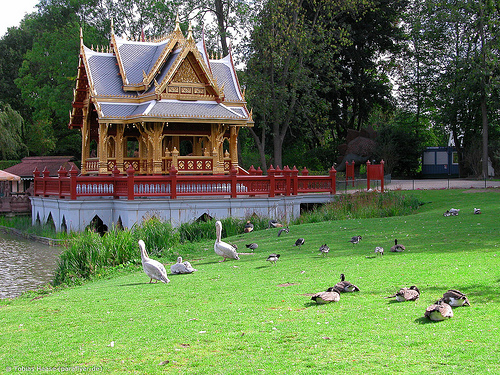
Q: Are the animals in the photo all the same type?
A: No, they are birds and ducks.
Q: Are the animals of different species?
A: Yes, they are birds and ducks.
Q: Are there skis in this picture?
A: No, there are no skis.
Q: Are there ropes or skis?
A: No, there are no skis or ropes.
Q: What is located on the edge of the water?
A: The plants are on the edge of the water.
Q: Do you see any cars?
A: No, there are no cars.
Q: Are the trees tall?
A: Yes, the trees are tall.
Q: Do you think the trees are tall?
A: Yes, the trees are tall.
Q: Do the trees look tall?
A: Yes, the trees are tall.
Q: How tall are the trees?
A: The trees are tall.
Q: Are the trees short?
A: No, the trees are tall.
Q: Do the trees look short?
A: No, the trees are tall.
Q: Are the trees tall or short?
A: The trees are tall.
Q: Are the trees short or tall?
A: The trees are tall.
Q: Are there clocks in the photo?
A: No, there are no clocks.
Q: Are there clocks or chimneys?
A: No, there are no clocks or chimneys.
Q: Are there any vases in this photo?
A: No, there are no vases.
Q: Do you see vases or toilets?
A: No, there are no vases or toilets.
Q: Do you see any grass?
A: Yes, there is grass.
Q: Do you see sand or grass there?
A: Yes, there is grass.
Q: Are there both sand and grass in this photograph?
A: No, there is grass but no sand.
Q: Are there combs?
A: No, there are no combs.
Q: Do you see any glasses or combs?
A: No, there are no combs or glasses.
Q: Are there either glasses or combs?
A: No, there are no combs or glasses.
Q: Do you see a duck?
A: Yes, there is a duck.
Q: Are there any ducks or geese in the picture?
A: Yes, there is a duck.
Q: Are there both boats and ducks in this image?
A: No, there is a duck but no boats.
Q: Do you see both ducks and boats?
A: No, there is a duck but no boats.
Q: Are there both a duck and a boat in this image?
A: No, there is a duck but no boats.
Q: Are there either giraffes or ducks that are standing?
A: Yes, the duck is standing.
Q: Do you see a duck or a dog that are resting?
A: Yes, the duck is resting.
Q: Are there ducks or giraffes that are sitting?
A: Yes, the duck is sitting.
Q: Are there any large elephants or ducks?
A: Yes, there is a large duck.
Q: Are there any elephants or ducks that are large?
A: Yes, the duck is large.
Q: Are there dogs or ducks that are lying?
A: Yes, the duck is lying.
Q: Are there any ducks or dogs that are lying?
A: Yes, the duck is lying.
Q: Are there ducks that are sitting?
A: Yes, there is a duck that is sitting.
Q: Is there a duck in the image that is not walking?
A: Yes, there is a duck that is sitting.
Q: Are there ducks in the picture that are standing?
A: Yes, there is a duck that is standing.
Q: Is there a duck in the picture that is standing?
A: Yes, there is a duck that is standing.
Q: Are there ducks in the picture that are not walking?
A: Yes, there is a duck that is standing.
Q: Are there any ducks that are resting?
A: Yes, there is a duck that is resting.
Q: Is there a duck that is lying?
A: Yes, there is a duck that is lying.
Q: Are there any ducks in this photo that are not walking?
A: Yes, there is a duck that is lying.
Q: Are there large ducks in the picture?
A: Yes, there is a large duck.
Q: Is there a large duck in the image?
A: Yes, there is a large duck.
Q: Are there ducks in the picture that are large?
A: Yes, there is a duck that is large.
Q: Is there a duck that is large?
A: Yes, there is a duck that is large.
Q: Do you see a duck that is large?
A: Yes, there is a duck that is large.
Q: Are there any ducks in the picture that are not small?
A: Yes, there is a large duck.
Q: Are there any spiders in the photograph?
A: No, there are no spiders.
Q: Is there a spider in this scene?
A: No, there are no spiders.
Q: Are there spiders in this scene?
A: No, there are no spiders.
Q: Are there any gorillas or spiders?
A: No, there are no spiders or gorillas.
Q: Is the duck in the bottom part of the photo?
A: Yes, the duck is in the bottom of the image.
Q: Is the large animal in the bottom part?
A: Yes, the duck is in the bottom of the image.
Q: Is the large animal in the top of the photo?
A: No, the duck is in the bottom of the image.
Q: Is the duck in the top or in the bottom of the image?
A: The duck is in the bottom of the image.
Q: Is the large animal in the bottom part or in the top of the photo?
A: The duck is in the bottom of the image.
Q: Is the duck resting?
A: Yes, the duck is resting.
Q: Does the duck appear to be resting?
A: Yes, the duck is resting.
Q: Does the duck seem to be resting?
A: Yes, the duck is resting.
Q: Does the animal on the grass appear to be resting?
A: Yes, the duck is resting.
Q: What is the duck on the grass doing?
A: The duck is resting.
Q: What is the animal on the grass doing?
A: The duck is resting.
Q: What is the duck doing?
A: The duck is resting.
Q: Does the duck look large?
A: Yes, the duck is large.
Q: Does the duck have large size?
A: Yes, the duck is large.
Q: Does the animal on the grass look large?
A: Yes, the duck is large.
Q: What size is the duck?
A: The duck is large.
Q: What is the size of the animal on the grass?
A: The duck is large.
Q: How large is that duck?
A: The duck is large.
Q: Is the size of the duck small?
A: No, the duck is large.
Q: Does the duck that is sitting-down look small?
A: No, the duck is large.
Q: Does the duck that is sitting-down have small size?
A: No, the duck is large.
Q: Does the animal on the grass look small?
A: No, the duck is large.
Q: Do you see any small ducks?
A: No, there is a duck but it is large.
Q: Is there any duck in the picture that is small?
A: No, there is a duck but it is large.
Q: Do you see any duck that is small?
A: No, there is a duck but it is large.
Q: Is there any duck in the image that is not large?
A: No, there is a duck but it is large.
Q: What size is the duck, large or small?
A: The duck is large.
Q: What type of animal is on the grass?
A: The animal is a duck.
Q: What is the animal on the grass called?
A: The animal is a duck.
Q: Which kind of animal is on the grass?
A: The animal is a duck.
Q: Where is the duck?
A: The duck is on the grass.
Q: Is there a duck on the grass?
A: Yes, there is a duck on the grass.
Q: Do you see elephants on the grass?
A: No, there is a duck on the grass.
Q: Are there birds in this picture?
A: Yes, there are birds.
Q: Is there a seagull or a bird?
A: Yes, there are birds.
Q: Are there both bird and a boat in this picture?
A: No, there are birds but no boats.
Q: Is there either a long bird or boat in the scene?
A: Yes, there are long birds.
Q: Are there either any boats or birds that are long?
A: Yes, the birds are long.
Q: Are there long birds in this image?
A: Yes, there are long birds.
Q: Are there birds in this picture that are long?
A: Yes, there are birds that are long.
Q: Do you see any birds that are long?
A: Yes, there are birds that are long.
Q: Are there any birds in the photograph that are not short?
A: Yes, there are long birds.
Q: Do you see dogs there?
A: No, there are no dogs.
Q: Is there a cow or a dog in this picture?
A: No, there are no dogs or cows.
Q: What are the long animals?
A: The animals are birds.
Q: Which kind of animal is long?
A: The animal is birds.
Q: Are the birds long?
A: Yes, the birds are long.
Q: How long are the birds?
A: The birds are long.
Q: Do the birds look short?
A: No, the birds are long.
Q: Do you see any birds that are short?
A: No, there are birds but they are long.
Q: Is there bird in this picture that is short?
A: No, there are birds but they are long.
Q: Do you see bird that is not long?
A: No, there are birds but they are long.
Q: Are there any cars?
A: No, there are no cars.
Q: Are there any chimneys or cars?
A: No, there are no cars or chimneys.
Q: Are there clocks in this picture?
A: No, there are no clocks.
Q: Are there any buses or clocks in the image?
A: No, there are no clocks or buses.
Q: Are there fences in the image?
A: Yes, there is a fence.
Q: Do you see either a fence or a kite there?
A: Yes, there is a fence.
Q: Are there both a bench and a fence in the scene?
A: No, there is a fence but no benches.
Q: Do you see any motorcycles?
A: No, there are no motorcycles.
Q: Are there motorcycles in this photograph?
A: No, there are no motorcycles.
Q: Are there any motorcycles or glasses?
A: No, there are no motorcycles or glasses.